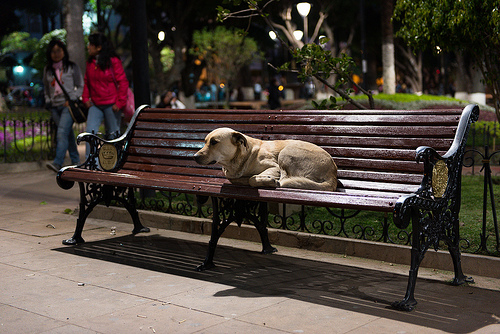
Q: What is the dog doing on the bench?
A: Sitting.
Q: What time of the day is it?
A: Night.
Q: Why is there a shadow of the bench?
A: The light is shining in that area.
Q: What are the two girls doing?
A: Walking and talking.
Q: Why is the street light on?
A: It is nighttime.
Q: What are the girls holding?
A: Bags.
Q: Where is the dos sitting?
A: Bench.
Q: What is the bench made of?
A: Wood.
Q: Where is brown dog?
A: On bench.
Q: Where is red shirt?
A: On girl on right.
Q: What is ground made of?
A: Cement.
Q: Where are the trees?
A: Behind bench in the distance.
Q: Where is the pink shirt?
A: Girl on the left.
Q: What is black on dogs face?
A: Nose.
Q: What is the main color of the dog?
A: Brown.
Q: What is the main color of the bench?
A: Brown.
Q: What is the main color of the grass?
A: Green.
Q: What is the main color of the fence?
A: Black.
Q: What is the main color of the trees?
A: Green.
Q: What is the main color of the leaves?
A: Green.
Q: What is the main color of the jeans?
A: Blue.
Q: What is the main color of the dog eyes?
A: Black.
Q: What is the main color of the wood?
A: Brown.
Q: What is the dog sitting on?
A: Bench.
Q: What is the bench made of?
A: Wood and metal.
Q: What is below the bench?
A: Shadows.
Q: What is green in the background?
A: Trees.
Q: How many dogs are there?
A: One.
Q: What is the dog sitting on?
A: A bench.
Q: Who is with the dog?
A: It's alone.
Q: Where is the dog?
A: In a park.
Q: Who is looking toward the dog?
A: The woman in the gray jacket.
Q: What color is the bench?
A: Brown.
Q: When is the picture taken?
A: At night.